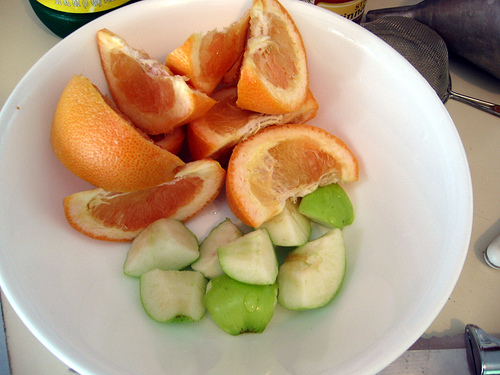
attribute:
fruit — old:
[68, 32, 353, 324]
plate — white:
[6, 4, 465, 371]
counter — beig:
[1, 3, 498, 335]